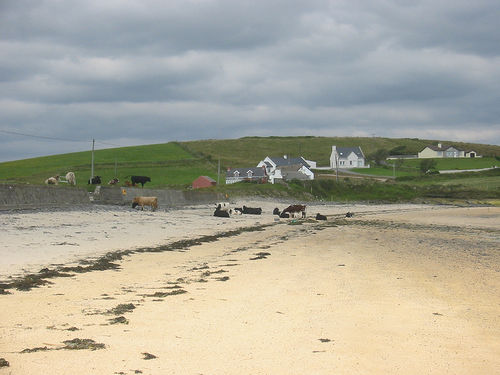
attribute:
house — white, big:
[215, 143, 326, 190]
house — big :
[417, 139, 477, 159]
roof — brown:
[416, 141, 465, 151]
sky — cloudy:
[2, 0, 499, 147]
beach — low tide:
[5, 200, 499, 373]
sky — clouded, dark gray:
[59, 10, 335, 100]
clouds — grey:
[2, 0, 497, 120]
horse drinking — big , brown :
[124, 192, 161, 213]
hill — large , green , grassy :
[0, 135, 497, 187]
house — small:
[192, 174, 215, 189]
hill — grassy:
[177, 121, 307, 181]